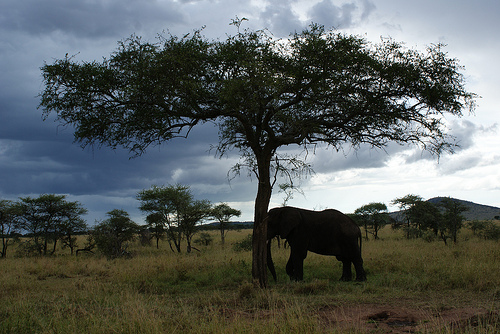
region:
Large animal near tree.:
[251, 196, 391, 300]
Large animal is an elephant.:
[232, 204, 380, 297]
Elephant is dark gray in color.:
[239, 210, 369, 325]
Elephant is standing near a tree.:
[235, 207, 293, 327]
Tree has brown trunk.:
[234, 157, 298, 330]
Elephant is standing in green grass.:
[271, 247, 406, 315]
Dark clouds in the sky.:
[56, 139, 121, 209]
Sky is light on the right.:
[331, 140, 481, 207]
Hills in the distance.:
[396, 182, 475, 243]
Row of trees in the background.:
[13, 200, 210, 267]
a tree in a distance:
[148, 187, 184, 253]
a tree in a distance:
[208, 195, 239, 245]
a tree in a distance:
[173, 182, 217, 258]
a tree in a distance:
[355, 192, 385, 239]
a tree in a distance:
[389, 187, 417, 244]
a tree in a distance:
[430, 181, 467, 243]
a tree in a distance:
[0, 194, 32, 266]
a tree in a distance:
[17, 191, 59, 256]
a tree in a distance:
[51, 194, 81, 245]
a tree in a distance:
[86, 199, 132, 255]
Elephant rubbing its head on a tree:
[226, 181, 413, 303]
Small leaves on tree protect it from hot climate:
[25, 13, 494, 176]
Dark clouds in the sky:
[3, 2, 247, 229]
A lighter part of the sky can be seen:
[224, 3, 499, 215]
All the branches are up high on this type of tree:
[114, 31, 399, 294]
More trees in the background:
[2, 172, 498, 259]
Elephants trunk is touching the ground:
[246, 199, 302, 304]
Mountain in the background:
[318, 189, 498, 234]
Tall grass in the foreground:
[3, 252, 335, 332]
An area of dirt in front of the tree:
[227, 267, 496, 329]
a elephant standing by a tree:
[207, 177, 375, 318]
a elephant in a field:
[13, 31, 461, 301]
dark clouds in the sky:
[43, 133, 246, 210]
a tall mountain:
[396, 190, 497, 238]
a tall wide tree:
[23, 32, 465, 313]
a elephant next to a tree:
[210, 194, 365, 302]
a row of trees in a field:
[0, 180, 246, 275]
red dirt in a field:
[256, 296, 482, 331]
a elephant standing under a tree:
[58, 36, 459, 307]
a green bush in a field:
[65, 224, 135, 268]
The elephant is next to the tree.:
[251, 207, 424, 297]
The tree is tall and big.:
[95, 37, 464, 264]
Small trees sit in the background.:
[25, 186, 217, 256]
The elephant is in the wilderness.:
[202, 179, 419, 286]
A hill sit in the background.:
[396, 178, 493, 230]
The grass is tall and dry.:
[105, 278, 302, 325]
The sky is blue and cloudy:
[35, 51, 227, 195]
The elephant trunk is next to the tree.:
[254, 208, 296, 268]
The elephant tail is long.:
[351, 226, 370, 265]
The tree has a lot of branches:
[170, 56, 442, 155]